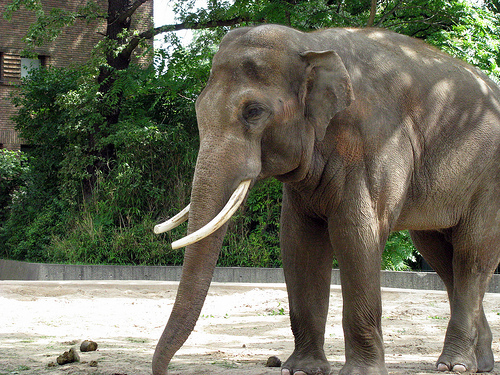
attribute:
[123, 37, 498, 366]
elephant — large, male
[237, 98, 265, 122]
eye — large, black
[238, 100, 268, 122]
eye — dark grey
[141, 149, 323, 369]
trunk — long, grey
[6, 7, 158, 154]
building — brown 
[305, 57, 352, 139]
ear — large, flappy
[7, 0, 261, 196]
tree — large , brown  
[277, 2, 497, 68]
tree — brown  , large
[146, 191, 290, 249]
tusk — ivory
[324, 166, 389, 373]
leg — tall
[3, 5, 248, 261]
tree — large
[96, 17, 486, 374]
elephant — gray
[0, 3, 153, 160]
building — large, brick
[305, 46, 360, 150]
ear — floppy, thin, grey, elephant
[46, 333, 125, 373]
poop — elephant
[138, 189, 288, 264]
tusks — white, elephant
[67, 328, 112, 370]
excrement — elephant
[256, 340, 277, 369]
excrement — elephant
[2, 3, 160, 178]
building — old , stone 